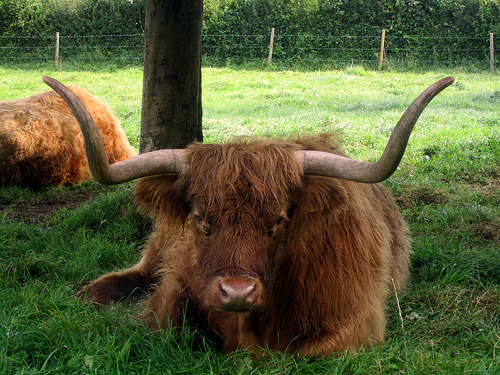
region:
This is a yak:
[23, 54, 448, 369]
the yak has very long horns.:
[57, 98, 459, 195]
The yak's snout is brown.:
[194, 251, 285, 316]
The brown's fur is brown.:
[108, 118, 398, 356]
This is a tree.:
[137, 7, 211, 149]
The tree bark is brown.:
[148, 40, 203, 147]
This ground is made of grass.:
[244, 63, 376, 129]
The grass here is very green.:
[228, 58, 377, 136]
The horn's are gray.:
[291, 130, 391, 188]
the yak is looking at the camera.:
[148, 120, 338, 323]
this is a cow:
[56, 97, 446, 345]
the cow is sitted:
[107, 124, 393, 355]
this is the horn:
[294, 68, 461, 183]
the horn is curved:
[303, 61, 459, 174]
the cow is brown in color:
[301, 190, 380, 299]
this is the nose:
[216, 273, 261, 309]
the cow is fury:
[188, 139, 285, 208]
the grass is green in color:
[431, 248, 491, 373]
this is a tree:
[140, 10, 202, 141]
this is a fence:
[308, 35, 364, 65]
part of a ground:
[424, 280, 445, 315]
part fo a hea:
[231, 212, 247, 234]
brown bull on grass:
[73, 4, 431, 354]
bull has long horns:
[77, 57, 433, 190]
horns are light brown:
[303, 46, 459, 183]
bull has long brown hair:
[195, 142, 429, 344]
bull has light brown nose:
[230, 282, 262, 314]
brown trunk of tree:
[140, 1, 197, 174]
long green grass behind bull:
[231, 70, 492, 229]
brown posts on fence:
[250, 27, 487, 95]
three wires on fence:
[252, 30, 487, 85]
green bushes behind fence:
[221, 2, 499, 77]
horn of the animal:
[354, 72, 459, 190]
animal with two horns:
[78, 103, 449, 324]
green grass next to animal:
[408, 300, 461, 357]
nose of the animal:
[177, 255, 271, 351]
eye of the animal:
[167, 193, 222, 253]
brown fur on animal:
[323, 243, 378, 297]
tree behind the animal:
[115, 23, 268, 95]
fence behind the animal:
[298, 20, 378, 85]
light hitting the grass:
[262, 78, 319, 109]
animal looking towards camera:
[67, 104, 427, 354]